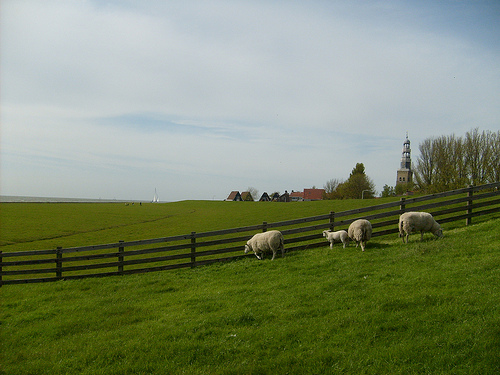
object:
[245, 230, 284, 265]
sheep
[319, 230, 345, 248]
sheep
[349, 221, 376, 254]
sheep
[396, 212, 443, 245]
sheep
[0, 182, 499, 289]
fence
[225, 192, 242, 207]
house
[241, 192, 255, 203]
house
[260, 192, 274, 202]
house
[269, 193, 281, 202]
house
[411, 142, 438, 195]
trees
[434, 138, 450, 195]
tree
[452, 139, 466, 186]
tree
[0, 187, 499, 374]
hill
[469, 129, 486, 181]
tree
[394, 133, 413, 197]
building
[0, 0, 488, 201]
sky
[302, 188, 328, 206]
building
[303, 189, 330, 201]
roof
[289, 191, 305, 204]
building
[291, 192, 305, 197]
roof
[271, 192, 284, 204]
building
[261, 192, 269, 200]
roof